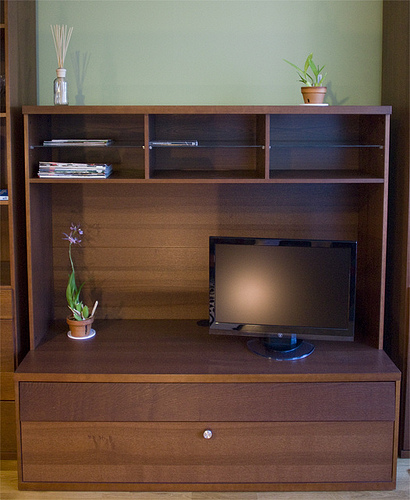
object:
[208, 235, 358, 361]
monitor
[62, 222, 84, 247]
flower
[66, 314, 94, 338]
pot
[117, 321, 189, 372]
desk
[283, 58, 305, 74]
leaves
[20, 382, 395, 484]
drawer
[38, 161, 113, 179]
magazines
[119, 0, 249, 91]
wall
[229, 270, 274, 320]
light shining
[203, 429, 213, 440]
knob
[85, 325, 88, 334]
spot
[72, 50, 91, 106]
shadows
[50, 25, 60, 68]
sticks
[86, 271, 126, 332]
shadow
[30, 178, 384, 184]
shelf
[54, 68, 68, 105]
bottle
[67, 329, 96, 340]
plate